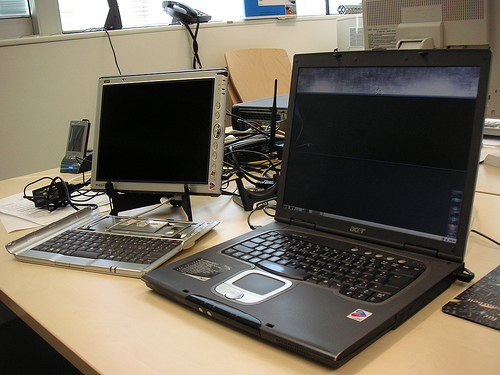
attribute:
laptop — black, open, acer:
[141, 49, 493, 370]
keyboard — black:
[223, 230, 427, 305]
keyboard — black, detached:
[30, 228, 183, 265]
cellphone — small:
[64, 120, 91, 161]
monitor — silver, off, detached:
[89, 68, 228, 197]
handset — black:
[163, 0, 199, 20]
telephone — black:
[164, 0, 211, 26]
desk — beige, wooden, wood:
[0, 124, 498, 375]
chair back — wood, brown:
[223, 48, 291, 104]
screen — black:
[93, 78, 215, 186]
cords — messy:
[22, 111, 286, 212]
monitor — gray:
[362, 1, 499, 120]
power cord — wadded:
[23, 176, 99, 213]